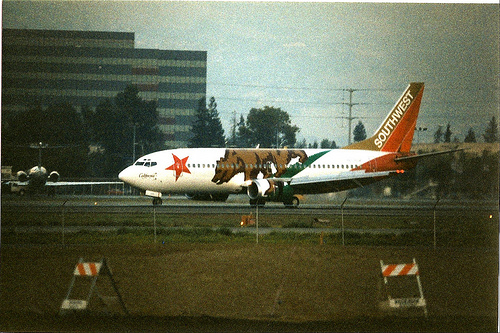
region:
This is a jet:
[54, 89, 486, 213]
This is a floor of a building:
[7, 36, 211, 66]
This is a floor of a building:
[7, 58, 208, 83]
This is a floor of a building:
[7, 73, 207, 98]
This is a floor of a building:
[10, 96, 210, 114]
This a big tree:
[111, 82, 166, 186]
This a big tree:
[190, 96, 238, 167]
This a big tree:
[237, 99, 298, 174]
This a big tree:
[354, 116, 366, 154]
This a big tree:
[41, 96, 82, 177]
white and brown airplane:
[120, 84, 433, 202]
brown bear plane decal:
[216, 148, 309, 185]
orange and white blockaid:
[63, 259, 125, 311]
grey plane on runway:
[8, 160, 120, 201]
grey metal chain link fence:
[6, 200, 497, 247]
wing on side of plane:
[251, 172, 414, 184]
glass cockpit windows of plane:
[134, 160, 158, 169]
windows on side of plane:
[176, 162, 368, 171]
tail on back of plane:
[376, 80, 424, 150]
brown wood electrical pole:
[343, 88, 359, 143]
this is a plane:
[120, 75, 462, 225]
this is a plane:
[0, 145, 138, 214]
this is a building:
[3, 28, 205, 208]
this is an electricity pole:
[330, 85, 363, 198]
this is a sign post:
[375, 245, 430, 317]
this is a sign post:
[52, 242, 127, 327]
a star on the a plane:
[161, 140, 201, 188]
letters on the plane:
[370, 125, 396, 156]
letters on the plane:
[373, 123, 403, 138]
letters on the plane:
[388, 99, 409, 132]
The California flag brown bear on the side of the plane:
[213, 138, 328, 186]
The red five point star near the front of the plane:
[168, 153, 191, 185]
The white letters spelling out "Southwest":
[370, 77, 415, 151]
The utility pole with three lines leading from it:
[333, 83, 370, 154]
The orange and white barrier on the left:
[60, 255, 130, 320]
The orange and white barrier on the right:
[377, 255, 427, 313]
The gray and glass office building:
[12, 28, 204, 158]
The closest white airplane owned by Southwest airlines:
[115, 77, 466, 205]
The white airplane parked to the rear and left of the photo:
[5, 133, 128, 208]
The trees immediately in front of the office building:
[8, 88, 223, 168]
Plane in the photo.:
[120, 80, 427, 203]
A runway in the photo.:
[198, 202, 311, 212]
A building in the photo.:
[62, 33, 198, 98]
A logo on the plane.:
[162, 155, 190, 181]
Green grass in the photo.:
[160, 228, 242, 238]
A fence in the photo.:
[247, 209, 354, 241]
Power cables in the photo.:
[256, 86, 336, 116]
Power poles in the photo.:
[345, 81, 355, 144]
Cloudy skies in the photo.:
[249, 9, 369, 64]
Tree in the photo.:
[188, 97, 231, 148]